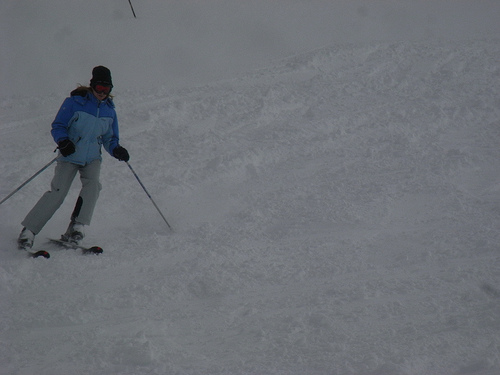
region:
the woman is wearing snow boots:
[17, 230, 44, 257]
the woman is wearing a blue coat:
[50, 100, 112, 161]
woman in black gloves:
[112, 143, 131, 162]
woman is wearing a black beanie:
[89, 66, 119, 81]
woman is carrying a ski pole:
[121, 154, 186, 237]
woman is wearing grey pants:
[41, 164, 107, 232]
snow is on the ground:
[232, 186, 367, 305]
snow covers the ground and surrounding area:
[234, 140, 411, 265]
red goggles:
[93, 81, 109, 93]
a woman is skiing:
[23, 69, 165, 261]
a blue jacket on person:
[28, 94, 136, 166]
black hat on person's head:
[86, 62, 125, 84]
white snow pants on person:
[8, 158, 108, 233]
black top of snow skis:
[10, 243, 115, 264]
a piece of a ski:
[121, 0, 153, 25]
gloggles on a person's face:
[88, 78, 114, 100]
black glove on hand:
[108, 145, 137, 160]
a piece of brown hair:
[103, 93, 118, 103]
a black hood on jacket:
[52, 84, 90, 106]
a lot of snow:
[189, 39, 419, 366]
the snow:
[235, 169, 439, 324]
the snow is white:
[226, 180, 441, 335]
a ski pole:
[130, 175, 207, 235]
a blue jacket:
[69, 98, 106, 144]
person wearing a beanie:
[90, 62, 111, 79]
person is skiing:
[17, 65, 142, 254]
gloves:
[57, 136, 77, 157]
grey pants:
[46, 170, 76, 193]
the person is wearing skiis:
[75, 231, 115, 264]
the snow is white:
[274, 155, 454, 293]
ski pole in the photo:
[114, 165, 181, 231]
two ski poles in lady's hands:
[0, 134, 200, 234]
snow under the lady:
[118, 247, 203, 316]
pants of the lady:
[23, 168, 120, 242]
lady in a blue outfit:
[2, 46, 189, 242]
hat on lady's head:
[86, 47, 127, 92]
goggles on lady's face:
[79, 71, 129, 109]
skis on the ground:
[0, 218, 120, 265]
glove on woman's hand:
[38, 130, 87, 172]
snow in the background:
[229, 17, 430, 169]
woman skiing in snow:
[8, 50, 246, 309]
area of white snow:
[245, 133, 383, 235]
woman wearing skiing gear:
[19, 55, 159, 256]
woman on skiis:
[13, 60, 185, 287]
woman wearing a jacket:
[43, 78, 125, 174]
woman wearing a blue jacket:
[46, 84, 138, 182]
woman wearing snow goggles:
[88, 78, 123, 98]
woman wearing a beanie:
[86, 62, 121, 90]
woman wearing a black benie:
[85, 60, 117, 87]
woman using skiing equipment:
[8, 41, 202, 286]